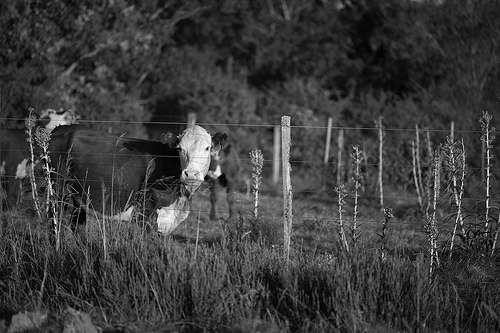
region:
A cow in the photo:
[50, 110, 233, 205]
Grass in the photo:
[238, 263, 347, 318]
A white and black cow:
[42, 113, 213, 221]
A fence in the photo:
[232, 100, 417, 274]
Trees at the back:
[223, 35, 390, 100]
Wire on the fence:
[286, 123, 402, 198]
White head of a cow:
[177, 129, 213, 184]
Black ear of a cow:
[206, 127, 233, 152]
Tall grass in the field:
[207, 233, 297, 300]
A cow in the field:
[55, 130, 215, 220]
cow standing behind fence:
[40, 103, 270, 297]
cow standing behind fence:
[32, 91, 259, 313]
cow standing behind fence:
[47, 86, 251, 286]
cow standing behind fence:
[27, 75, 257, 279]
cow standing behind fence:
[31, 89, 238, 289]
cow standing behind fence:
[34, 93, 239, 261]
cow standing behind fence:
[47, 61, 242, 248]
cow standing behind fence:
[37, 82, 242, 283]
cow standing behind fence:
[31, 73, 256, 270]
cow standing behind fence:
[40, 85, 262, 253]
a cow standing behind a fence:
[0, 125, 232, 237]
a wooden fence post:
[274, 112, 296, 252]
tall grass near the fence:
[1, 203, 498, 332]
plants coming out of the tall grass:
[23, 103, 65, 223]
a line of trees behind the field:
[1, 0, 499, 155]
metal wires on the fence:
[1, 114, 283, 225]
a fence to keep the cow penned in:
[1, 108, 499, 249]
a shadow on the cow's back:
[123, 135, 183, 188]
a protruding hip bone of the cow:
[62, 126, 82, 151]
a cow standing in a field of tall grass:
[40, 116, 230, 236]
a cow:
[76, 114, 221, 242]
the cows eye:
[198, 142, 211, 153]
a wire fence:
[254, 117, 282, 237]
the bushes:
[194, 64, 243, 122]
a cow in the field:
[70, 125, 215, 240]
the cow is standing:
[70, 106, 220, 237]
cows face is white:
[176, 132, 211, 182]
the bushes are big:
[193, 61, 320, 117]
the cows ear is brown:
[213, 132, 235, 155]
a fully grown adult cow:
[28, 103, 219, 235]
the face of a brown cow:
[165, 112, 229, 197]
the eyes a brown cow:
[172, 141, 219, 156]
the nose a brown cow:
[181, 159, 202, 180]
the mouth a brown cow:
[182, 175, 199, 189]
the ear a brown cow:
[200, 122, 237, 152]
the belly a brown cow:
[77, 169, 125, 241]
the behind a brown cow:
[32, 115, 83, 157]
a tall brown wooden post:
[257, 108, 311, 240]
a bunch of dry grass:
[205, 251, 275, 312]